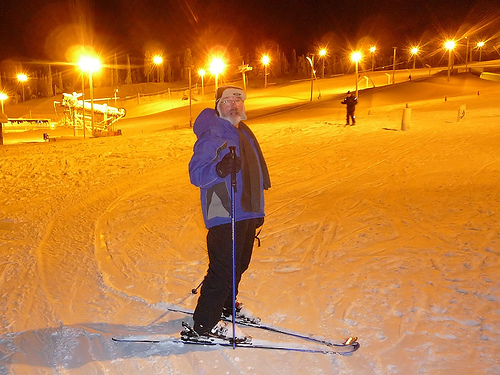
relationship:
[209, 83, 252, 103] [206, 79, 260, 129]
cap on man's head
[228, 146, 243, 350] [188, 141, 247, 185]
ski pole in man's hand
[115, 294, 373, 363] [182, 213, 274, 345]
ski on man's foot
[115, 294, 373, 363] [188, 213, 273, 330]
ski on man's foot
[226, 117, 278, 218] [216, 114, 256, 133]
scarf around man's neck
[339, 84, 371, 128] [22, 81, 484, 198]
man in background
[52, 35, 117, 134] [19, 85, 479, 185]
street light in background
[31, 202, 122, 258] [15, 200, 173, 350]
track marks on snow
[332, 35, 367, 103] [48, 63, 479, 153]
street light in background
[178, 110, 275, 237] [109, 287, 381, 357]
blue jacket on skis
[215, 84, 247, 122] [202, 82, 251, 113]
brown fur lined hat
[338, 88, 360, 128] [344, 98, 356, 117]
man wearing black snow suit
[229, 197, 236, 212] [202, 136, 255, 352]
blue shaft ski pole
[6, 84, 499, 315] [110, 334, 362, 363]
snow covered ski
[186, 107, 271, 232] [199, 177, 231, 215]
blue jacket with black and gray pattern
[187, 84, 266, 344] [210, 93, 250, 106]
man wearing glasses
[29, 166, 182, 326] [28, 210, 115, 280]
packed snow with ski marks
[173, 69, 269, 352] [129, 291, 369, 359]
man wearing skis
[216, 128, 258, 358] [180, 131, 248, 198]
ski pole in a man's hand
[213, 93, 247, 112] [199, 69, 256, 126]
glasses on man's head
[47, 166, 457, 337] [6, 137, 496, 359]
snow on ground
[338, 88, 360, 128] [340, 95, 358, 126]
man wearing snow suit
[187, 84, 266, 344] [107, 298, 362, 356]
man standing on skis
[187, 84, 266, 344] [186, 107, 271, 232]
man wearing blue jacket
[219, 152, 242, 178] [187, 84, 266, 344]
glove on man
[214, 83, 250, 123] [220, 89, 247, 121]
cap on head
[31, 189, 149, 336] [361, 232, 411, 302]
track marks in snow